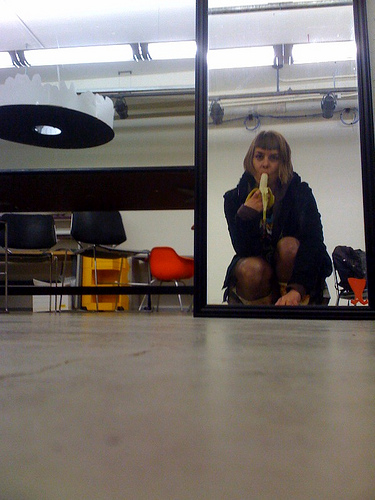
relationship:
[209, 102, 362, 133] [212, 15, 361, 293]
wires attached to wall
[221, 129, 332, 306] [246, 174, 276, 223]
woman eating banana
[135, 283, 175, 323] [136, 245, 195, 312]
legs are on chair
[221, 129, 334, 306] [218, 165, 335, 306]
woman wearing coat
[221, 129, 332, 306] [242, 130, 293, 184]
woman has hair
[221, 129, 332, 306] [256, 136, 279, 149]
woman has bangs